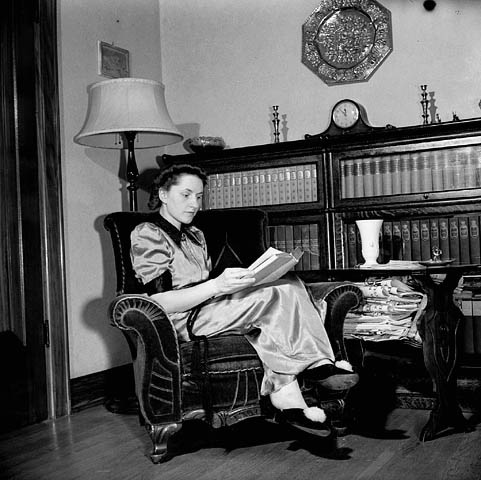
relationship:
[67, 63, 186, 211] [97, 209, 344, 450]
lamp behind chair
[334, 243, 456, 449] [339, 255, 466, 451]
paper on stand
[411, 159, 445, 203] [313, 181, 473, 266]
book on shelf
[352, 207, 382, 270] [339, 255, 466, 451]
vase on stand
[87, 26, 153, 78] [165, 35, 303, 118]
picture on wall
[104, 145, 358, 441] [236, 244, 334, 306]
woman with book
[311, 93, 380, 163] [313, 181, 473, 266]
clock on shelf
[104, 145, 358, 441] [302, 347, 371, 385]
woman with shoes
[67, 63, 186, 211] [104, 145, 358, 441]
lamp behind woman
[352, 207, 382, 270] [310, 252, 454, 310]
vase on desk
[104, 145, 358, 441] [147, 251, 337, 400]
woman in dress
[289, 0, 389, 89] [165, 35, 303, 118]
plate on wall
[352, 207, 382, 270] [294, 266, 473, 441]
vase on desk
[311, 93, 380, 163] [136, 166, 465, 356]
clock on bookshelf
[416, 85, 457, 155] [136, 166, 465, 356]
candle on bookshelf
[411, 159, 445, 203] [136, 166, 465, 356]
book on bookshelf